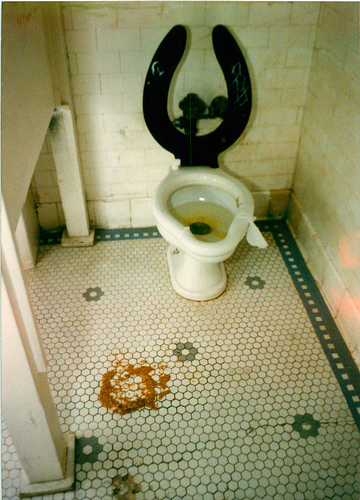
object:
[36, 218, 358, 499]
border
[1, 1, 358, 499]
bathroom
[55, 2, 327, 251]
wall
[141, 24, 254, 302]
toilet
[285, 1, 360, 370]
tile wall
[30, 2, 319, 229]
tile wall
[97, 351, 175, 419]
vomit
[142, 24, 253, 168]
seat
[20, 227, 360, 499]
floor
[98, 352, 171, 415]
mud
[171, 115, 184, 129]
toilet handle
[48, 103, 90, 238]
leg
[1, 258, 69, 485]
leg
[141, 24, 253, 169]
toilet seat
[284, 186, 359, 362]
base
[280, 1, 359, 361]
wall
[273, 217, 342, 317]
tile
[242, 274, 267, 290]
flower pattern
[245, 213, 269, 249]
paper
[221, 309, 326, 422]
tile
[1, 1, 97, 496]
divider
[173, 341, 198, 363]
tile